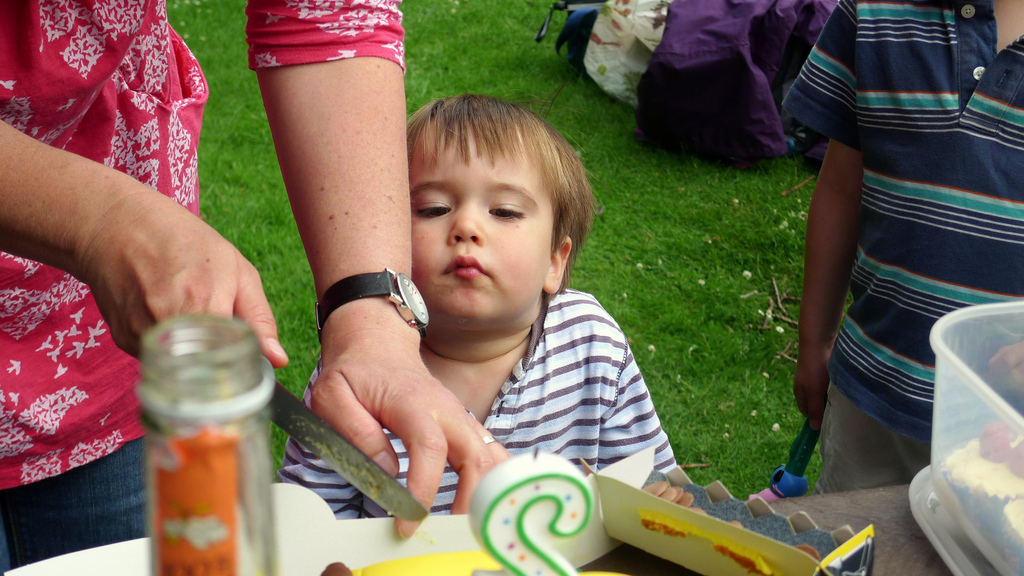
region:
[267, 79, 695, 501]
Young boy wearing striped shirt.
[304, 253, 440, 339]
Black and white watch around wrist.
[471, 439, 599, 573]
White and green candle with dots.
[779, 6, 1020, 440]
Green and white striped blue shirt.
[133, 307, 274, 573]
Glass container with orange label.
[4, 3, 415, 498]
Red shirt with white pattern.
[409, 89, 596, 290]
Short brown hair.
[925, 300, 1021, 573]
Plastic container holding cupcakes.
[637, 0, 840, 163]
Purple bag laying on the ground.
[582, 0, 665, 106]
White bag laying on the ground.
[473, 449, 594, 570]
birthday candle with a number 2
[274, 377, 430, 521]
the sharp end of a knife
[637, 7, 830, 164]
dark purple fabric in the background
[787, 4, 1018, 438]
blue striped polo shirt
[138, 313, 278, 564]
glass container with an orange label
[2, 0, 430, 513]
Woman wearing pink shirt.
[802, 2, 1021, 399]
Blue shirt with red, white, and green stripes.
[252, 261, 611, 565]
Woman cutting birthday cake.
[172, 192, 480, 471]
Woman wearing black watch.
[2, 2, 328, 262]
Pink and white shirt.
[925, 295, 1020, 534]
Plastic container holding food.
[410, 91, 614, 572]
Young boy looking at cake.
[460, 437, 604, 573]
Candle in shape of a number.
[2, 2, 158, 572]
Woman wearing blue jeans.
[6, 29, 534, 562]
woman holding a knife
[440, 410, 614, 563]
a white number candle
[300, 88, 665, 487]
a little boy next to woman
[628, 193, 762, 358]
a patch of grass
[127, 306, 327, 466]
top of a bottle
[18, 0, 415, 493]
a red and white shirt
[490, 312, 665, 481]
a white and blue shirt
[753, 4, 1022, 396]
a blue striped shirt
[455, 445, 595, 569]
green trim on candle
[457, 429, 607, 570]
candle shaped as number two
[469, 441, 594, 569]
a green and white candle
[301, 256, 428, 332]
a black and gray wristwatch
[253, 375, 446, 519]
a long gray butter knife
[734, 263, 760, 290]
a small white flower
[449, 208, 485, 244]
the nose of a boy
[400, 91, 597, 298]
a boy's short cut brown hair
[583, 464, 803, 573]
a white cardboard box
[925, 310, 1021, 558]
a large plastic container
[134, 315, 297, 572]
a tall glass jar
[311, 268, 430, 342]
the watch has a black band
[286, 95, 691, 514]
the child has light brown hair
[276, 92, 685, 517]
the child is wearing a shirt with brown stripes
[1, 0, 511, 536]
the person holding the knife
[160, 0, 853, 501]
the lush, green grass